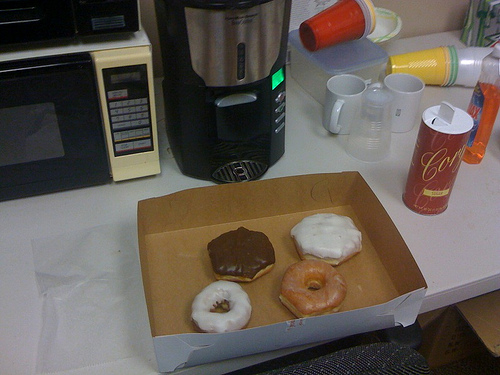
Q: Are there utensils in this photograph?
A: No, there are no utensils.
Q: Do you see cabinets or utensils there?
A: No, there are no utensils or cabinets.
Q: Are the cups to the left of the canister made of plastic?
A: Yes, the cups are made of plastic.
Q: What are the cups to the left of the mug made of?
A: The cups are made of plastic.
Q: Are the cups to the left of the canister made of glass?
A: No, the cups are made of plastic.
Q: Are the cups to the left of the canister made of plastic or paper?
A: The cups are made of plastic.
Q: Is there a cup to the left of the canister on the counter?
A: Yes, there are cups to the left of the canister.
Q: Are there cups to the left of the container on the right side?
A: Yes, there are cups to the left of the canister.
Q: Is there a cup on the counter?
A: Yes, there are cups on the counter.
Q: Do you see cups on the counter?
A: Yes, there are cups on the counter.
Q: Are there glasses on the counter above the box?
A: No, there are cups on the counter.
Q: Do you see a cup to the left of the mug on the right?
A: Yes, there are cups to the left of the mug.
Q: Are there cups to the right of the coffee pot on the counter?
A: Yes, there are cups to the right of the coffee pot.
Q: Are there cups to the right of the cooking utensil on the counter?
A: Yes, there are cups to the right of the coffee pot.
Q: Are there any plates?
A: No, there are no plates.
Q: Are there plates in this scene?
A: No, there are no plates.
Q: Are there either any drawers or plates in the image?
A: No, there are no plates or drawers.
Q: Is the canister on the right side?
A: Yes, the canister is on the right of the image.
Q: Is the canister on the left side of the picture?
A: No, the canister is on the right of the image.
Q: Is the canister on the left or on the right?
A: The canister is on the right of the image.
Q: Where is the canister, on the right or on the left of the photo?
A: The canister is on the right of the image.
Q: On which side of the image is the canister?
A: The canister is on the right of the image.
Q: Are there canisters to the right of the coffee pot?
A: Yes, there is a canister to the right of the coffee pot.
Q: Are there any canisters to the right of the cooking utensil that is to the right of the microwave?
A: Yes, there is a canister to the right of the coffee pot.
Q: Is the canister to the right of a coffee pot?
A: Yes, the canister is to the right of a coffee pot.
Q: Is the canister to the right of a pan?
A: No, the canister is to the right of a coffee pot.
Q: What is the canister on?
A: The canister is on the counter.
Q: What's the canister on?
A: The canister is on the counter.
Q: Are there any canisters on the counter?
A: Yes, there is a canister on the counter.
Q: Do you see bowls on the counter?
A: No, there is a canister on the counter.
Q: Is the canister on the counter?
A: Yes, the canister is on the counter.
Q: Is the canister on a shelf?
A: No, the canister is on the counter.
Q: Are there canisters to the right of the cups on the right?
A: Yes, there is a canister to the right of the cups.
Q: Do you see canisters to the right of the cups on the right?
A: Yes, there is a canister to the right of the cups.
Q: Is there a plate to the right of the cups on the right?
A: No, there is a canister to the right of the cups.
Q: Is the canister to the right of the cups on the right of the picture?
A: Yes, the canister is to the right of the cups.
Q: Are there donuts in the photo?
A: Yes, there are donuts.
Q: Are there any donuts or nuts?
A: Yes, there are donuts.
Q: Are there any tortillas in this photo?
A: No, there are no tortillas.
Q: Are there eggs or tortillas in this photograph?
A: No, there are no tortillas or eggs.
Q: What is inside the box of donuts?
A: The doughnuts are inside the box.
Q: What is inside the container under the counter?
A: The doughnuts are inside the box.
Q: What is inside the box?
A: The doughnuts are inside the box.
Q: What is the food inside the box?
A: The food is donuts.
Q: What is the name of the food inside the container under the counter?
A: The food is donuts.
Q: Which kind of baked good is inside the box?
A: The food is donuts.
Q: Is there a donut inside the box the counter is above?
A: Yes, there are donuts inside the box.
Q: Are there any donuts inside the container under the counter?
A: Yes, there are donuts inside the box.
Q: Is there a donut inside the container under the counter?
A: Yes, there are donuts inside the box.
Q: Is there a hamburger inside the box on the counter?
A: No, there are donuts inside the box.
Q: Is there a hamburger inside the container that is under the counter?
A: No, there are donuts inside the box.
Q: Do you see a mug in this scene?
A: Yes, there is a mug.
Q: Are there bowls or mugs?
A: Yes, there is a mug.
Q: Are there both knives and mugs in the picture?
A: No, there is a mug but no knives.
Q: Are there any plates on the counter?
A: No, there is a mug on the counter.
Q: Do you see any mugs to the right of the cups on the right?
A: Yes, there is a mug to the right of the cups.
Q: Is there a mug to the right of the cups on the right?
A: Yes, there is a mug to the right of the cups.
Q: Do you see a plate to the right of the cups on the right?
A: No, there is a mug to the right of the cups.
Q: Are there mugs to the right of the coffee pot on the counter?
A: Yes, there is a mug to the right of the coffee pot.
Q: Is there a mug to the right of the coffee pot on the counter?
A: Yes, there is a mug to the right of the coffee pot.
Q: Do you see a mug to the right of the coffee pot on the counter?
A: Yes, there is a mug to the right of the coffee pot.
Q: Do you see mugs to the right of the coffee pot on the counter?
A: Yes, there is a mug to the right of the coffee pot.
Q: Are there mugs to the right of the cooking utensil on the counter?
A: Yes, there is a mug to the right of the coffee pot.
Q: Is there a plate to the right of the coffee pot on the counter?
A: No, there is a mug to the right of the coffee pot.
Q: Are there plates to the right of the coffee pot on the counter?
A: No, there is a mug to the right of the coffee pot.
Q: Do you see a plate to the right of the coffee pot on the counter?
A: No, there is a mug to the right of the coffee pot.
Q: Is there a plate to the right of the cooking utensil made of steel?
A: No, there is a mug to the right of the coffee pot.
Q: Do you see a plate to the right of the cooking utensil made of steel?
A: No, there is a mug to the right of the coffee pot.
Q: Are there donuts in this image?
A: Yes, there is a donut.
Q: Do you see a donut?
A: Yes, there is a donut.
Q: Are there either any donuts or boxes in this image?
A: Yes, there is a donut.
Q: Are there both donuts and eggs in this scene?
A: No, there is a donut but no eggs.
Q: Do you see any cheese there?
A: No, there is no cheese.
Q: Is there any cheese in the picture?
A: No, there is no cheese.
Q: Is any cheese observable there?
A: No, there is no cheese.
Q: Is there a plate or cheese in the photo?
A: No, there are no cheese or plates.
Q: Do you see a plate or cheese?
A: No, there are no cheese or plates.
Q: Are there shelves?
A: No, there are no shelves.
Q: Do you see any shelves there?
A: No, there are no shelves.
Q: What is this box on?
A: The box is on the counter.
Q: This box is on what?
A: The box is on the counter.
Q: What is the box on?
A: The box is on the counter.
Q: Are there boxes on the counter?
A: Yes, there is a box on the counter.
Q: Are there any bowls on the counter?
A: No, there is a box on the counter.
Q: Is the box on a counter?
A: Yes, the box is on a counter.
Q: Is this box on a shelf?
A: No, the box is on a counter.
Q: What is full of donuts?
A: The box is full of donuts.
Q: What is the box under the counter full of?
A: The box is full of donuts.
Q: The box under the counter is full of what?
A: The box is full of donuts.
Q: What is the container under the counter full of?
A: The box is full of donuts.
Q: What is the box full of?
A: The box is full of donuts.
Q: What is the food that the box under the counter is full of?
A: The food is donuts.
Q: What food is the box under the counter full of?
A: The box is full of donuts.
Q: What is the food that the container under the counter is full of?
A: The food is donuts.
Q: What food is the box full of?
A: The box is full of donuts.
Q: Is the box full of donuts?
A: Yes, the box is full of donuts.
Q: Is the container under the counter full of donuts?
A: Yes, the box is full of donuts.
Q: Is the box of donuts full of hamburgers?
A: No, the box is full of donuts.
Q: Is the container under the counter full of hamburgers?
A: No, the box is full of donuts.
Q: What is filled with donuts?
A: The box is filled with donuts.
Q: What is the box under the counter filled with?
A: The box is filled with donuts.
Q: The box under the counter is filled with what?
A: The box is filled with donuts.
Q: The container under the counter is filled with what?
A: The box is filled with donuts.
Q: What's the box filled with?
A: The box is filled with donuts.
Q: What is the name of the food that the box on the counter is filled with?
A: The food is donuts.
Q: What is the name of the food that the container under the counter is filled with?
A: The food is donuts.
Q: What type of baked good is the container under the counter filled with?
A: The box is filled with donuts.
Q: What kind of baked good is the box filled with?
A: The box is filled with donuts.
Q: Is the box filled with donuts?
A: Yes, the box is filled with donuts.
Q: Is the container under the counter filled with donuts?
A: Yes, the box is filled with donuts.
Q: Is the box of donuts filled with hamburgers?
A: No, the box is filled with donuts.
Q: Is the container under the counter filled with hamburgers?
A: No, the box is filled with donuts.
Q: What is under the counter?
A: The box is under the counter.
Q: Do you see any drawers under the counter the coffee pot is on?
A: No, there is a box under the counter.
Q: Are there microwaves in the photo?
A: Yes, there is a microwave.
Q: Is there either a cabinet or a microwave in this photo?
A: Yes, there is a microwave.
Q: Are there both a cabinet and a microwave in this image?
A: No, there is a microwave but no cabinets.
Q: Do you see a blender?
A: No, there are no blenders.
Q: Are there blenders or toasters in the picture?
A: No, there are no blenders or toasters.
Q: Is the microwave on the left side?
A: Yes, the microwave is on the left of the image.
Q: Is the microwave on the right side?
A: No, the microwave is on the left of the image.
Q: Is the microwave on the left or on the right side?
A: The microwave is on the left of the image.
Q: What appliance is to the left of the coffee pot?
A: The appliance is a microwave.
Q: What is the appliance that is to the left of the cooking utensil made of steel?
A: The appliance is a microwave.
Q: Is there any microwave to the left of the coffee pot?
A: Yes, there is a microwave to the left of the coffee pot.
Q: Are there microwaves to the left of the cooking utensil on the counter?
A: Yes, there is a microwave to the left of the coffee pot.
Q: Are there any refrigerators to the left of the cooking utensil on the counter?
A: No, there is a microwave to the left of the coffee pot.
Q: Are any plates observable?
A: No, there are no plates.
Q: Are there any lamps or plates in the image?
A: No, there are no plates or lamps.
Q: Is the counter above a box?
A: Yes, the counter is above a box.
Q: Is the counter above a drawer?
A: No, the counter is above a box.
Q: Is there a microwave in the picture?
A: Yes, there is a microwave.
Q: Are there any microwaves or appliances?
A: Yes, there is a microwave.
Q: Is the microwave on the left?
A: Yes, the microwave is on the left of the image.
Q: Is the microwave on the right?
A: No, the microwave is on the left of the image.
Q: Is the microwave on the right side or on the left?
A: The microwave is on the left of the image.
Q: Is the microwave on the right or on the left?
A: The microwave is on the left of the image.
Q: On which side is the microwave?
A: The microwave is on the left of the image.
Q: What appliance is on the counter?
A: The appliance is a microwave.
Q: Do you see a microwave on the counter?
A: Yes, there is a microwave on the counter.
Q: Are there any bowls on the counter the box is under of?
A: No, there is a microwave on the counter.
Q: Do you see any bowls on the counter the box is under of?
A: No, there is a microwave on the counter.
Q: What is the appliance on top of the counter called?
A: The appliance is a microwave.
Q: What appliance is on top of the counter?
A: The appliance is a microwave.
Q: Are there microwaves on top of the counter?
A: Yes, there is a microwave on top of the counter.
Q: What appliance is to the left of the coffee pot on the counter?
A: The appliance is a microwave.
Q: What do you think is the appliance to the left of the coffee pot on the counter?
A: The appliance is a microwave.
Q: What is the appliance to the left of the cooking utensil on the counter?
A: The appliance is a microwave.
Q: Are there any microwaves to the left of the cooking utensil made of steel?
A: Yes, there is a microwave to the left of the coffee pot.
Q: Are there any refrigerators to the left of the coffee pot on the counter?
A: No, there is a microwave to the left of the coffee pot.